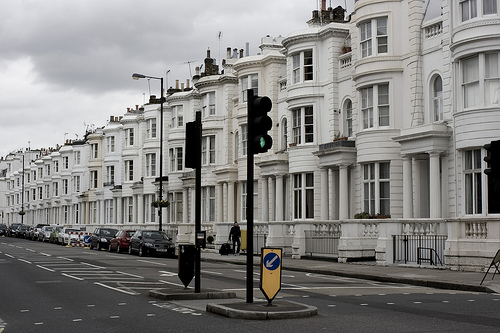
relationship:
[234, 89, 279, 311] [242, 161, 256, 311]
traffic signal on pole